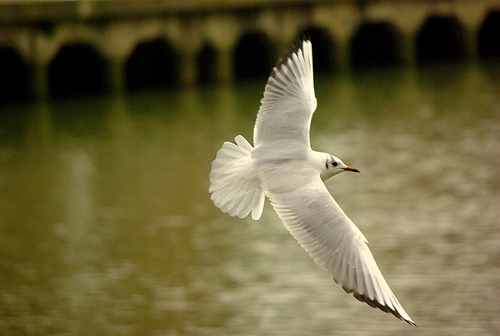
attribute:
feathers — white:
[318, 206, 395, 301]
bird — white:
[206, 37, 410, 323]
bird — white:
[200, 90, 427, 336]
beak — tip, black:
[345, 160, 361, 178]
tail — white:
[202, 122, 269, 238]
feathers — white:
[219, 184, 263, 216]